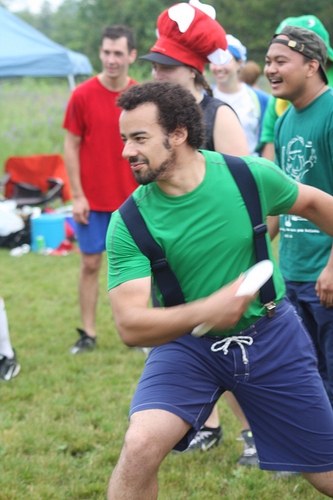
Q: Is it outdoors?
A: Yes, it is outdoors.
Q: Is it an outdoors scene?
A: Yes, it is outdoors.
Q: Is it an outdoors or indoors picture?
A: It is outdoors.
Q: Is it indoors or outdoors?
A: It is outdoors.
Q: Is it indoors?
A: No, it is outdoors.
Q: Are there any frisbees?
A: Yes, there is a frisbee.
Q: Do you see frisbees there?
A: Yes, there is a frisbee.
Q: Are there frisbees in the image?
A: Yes, there is a frisbee.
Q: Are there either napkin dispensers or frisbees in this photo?
A: Yes, there is a frisbee.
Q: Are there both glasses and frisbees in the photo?
A: No, there is a frisbee but no glasses.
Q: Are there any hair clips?
A: No, there are no hair clips.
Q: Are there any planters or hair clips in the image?
A: No, there are no hair clips or planters.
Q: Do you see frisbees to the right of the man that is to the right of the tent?
A: Yes, there is a frisbee to the right of the man.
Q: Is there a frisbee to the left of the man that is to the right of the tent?
A: No, the frisbee is to the right of the man.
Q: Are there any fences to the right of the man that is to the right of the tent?
A: No, there is a frisbee to the right of the man.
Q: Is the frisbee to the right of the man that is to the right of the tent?
A: Yes, the frisbee is to the right of the man.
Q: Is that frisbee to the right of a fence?
A: No, the frisbee is to the right of the man.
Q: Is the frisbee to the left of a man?
A: No, the frisbee is to the right of a man.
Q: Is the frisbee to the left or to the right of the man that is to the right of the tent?
A: The frisbee is to the right of the man.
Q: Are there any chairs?
A: Yes, there is a chair.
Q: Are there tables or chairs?
A: Yes, there is a chair.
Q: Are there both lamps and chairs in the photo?
A: No, there is a chair but no lamps.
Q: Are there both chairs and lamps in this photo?
A: No, there is a chair but no lamps.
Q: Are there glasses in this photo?
A: No, there are no glasses.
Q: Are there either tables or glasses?
A: No, there are no glasses or tables.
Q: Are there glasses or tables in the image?
A: No, there are no glasses or tables.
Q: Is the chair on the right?
A: No, the chair is on the left of the image.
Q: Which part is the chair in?
A: The chair is on the left of the image.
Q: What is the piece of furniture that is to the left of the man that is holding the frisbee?
A: The piece of furniture is a chair.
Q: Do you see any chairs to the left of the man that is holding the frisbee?
A: Yes, there is a chair to the left of the man.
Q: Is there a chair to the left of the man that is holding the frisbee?
A: Yes, there is a chair to the left of the man.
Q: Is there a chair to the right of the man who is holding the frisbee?
A: No, the chair is to the left of the man.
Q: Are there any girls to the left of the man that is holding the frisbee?
A: No, there is a chair to the left of the man.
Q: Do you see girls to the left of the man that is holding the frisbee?
A: No, there is a chair to the left of the man.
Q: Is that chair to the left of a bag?
A: No, the chair is to the left of a man.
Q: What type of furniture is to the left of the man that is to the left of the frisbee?
A: The piece of furniture is a chair.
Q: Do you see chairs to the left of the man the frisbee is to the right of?
A: Yes, there is a chair to the left of the man.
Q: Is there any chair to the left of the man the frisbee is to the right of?
A: Yes, there is a chair to the left of the man.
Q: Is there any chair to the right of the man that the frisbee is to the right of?
A: No, the chair is to the left of the man.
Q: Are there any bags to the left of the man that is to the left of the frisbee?
A: No, there is a chair to the left of the man.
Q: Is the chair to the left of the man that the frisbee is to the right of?
A: Yes, the chair is to the left of the man.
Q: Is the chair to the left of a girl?
A: No, the chair is to the left of the man.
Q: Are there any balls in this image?
A: No, there are no balls.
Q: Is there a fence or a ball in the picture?
A: No, there are no balls or fences.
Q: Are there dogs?
A: No, there are no dogs.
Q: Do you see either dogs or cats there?
A: No, there are no dogs or cats.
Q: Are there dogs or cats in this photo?
A: No, there are no dogs or cats.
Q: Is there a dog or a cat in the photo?
A: No, there are no dogs or cats.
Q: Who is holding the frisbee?
A: The man is holding the frisbee.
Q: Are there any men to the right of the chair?
A: Yes, there is a man to the right of the chair.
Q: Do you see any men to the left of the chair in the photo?
A: No, the man is to the right of the chair.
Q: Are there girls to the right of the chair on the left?
A: No, there is a man to the right of the chair.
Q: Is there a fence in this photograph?
A: No, there are no fences.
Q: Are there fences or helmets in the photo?
A: No, there are no fences or helmets.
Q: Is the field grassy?
A: Yes, the field is grassy.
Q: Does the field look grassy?
A: Yes, the field is grassy.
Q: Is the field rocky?
A: No, the field is grassy.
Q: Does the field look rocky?
A: No, the field is grassy.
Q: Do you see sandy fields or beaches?
A: No, there is a field but it is grassy.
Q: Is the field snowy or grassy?
A: The field is grassy.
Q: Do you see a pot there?
A: No, there are no pots.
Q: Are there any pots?
A: No, there are no pots.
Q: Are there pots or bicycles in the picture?
A: No, there are no pots or bicycles.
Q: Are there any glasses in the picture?
A: No, there are no glasses.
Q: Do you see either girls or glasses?
A: No, there are no glasses or girls.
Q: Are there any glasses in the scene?
A: No, there are no glasses.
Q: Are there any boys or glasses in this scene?
A: No, there are no glasses or boys.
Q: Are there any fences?
A: No, there are no fences.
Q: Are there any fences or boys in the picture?
A: No, there are no fences or boys.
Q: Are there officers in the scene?
A: No, there are no officers.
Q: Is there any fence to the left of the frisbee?
A: No, there is a man to the left of the frisbee.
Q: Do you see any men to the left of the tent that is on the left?
A: No, the man is to the right of the tent.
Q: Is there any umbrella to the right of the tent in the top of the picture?
A: No, there is a man to the right of the tent.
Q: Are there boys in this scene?
A: No, there are no boys.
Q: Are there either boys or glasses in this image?
A: No, there are no boys or glasses.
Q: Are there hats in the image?
A: Yes, there is a hat.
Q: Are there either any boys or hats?
A: Yes, there is a hat.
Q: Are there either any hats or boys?
A: Yes, there is a hat.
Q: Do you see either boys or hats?
A: Yes, there is a hat.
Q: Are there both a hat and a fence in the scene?
A: No, there is a hat but no fences.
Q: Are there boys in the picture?
A: No, there are no boys.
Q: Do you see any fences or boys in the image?
A: No, there are no boys or fences.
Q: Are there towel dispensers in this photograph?
A: No, there are no towel dispensers.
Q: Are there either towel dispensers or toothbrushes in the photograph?
A: No, there are no towel dispensers or toothbrushes.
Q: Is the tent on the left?
A: Yes, the tent is on the left of the image.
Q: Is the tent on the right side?
A: No, the tent is on the left of the image.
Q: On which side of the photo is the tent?
A: The tent is on the left of the image.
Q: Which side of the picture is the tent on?
A: The tent is on the left of the image.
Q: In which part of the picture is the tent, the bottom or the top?
A: The tent is in the top of the image.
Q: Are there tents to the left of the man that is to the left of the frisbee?
A: Yes, there is a tent to the left of the man.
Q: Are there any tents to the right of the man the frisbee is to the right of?
A: No, the tent is to the left of the man.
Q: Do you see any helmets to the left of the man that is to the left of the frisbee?
A: No, there is a tent to the left of the man.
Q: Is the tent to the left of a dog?
A: No, the tent is to the left of a man.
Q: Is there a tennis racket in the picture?
A: No, there are no rackets.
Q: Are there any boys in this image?
A: No, there are no boys.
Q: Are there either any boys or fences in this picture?
A: No, there are no boys or fences.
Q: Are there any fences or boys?
A: No, there are no boys or fences.